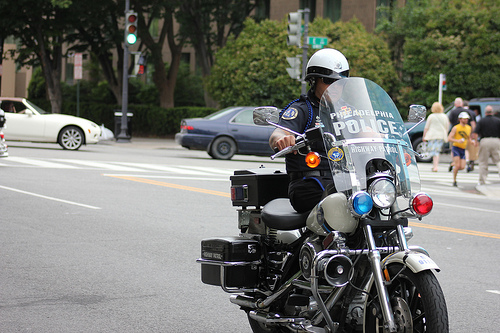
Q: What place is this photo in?
A: It is at the road.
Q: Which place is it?
A: It is a road.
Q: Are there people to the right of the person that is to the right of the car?
A: Yes, there is a person to the right of the man.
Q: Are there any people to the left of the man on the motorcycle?
A: No, the person is to the right of the man.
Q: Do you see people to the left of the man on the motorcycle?
A: No, the person is to the right of the man.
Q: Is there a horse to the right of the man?
A: No, there is a person to the right of the man.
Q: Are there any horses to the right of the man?
A: No, there is a person to the right of the man.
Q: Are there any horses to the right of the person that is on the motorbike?
A: No, there is a person to the right of the man.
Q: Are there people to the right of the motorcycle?
A: Yes, there is a person to the right of the motorcycle.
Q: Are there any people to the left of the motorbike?
A: No, the person is to the right of the motorbike.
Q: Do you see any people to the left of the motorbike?
A: No, the person is to the right of the motorbike.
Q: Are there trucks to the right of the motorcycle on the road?
A: No, there is a person to the right of the motorbike.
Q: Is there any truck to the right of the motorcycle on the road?
A: No, there is a person to the right of the motorbike.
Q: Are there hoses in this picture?
A: No, there are no hoses.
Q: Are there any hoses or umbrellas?
A: No, there are no hoses or umbrellas.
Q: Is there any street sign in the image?
A: Yes, there is a street sign.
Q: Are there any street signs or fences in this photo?
A: Yes, there is a street sign.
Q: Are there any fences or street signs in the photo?
A: Yes, there is a street sign.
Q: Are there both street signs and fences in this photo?
A: No, there is a street sign but no fences.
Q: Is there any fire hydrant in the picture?
A: No, there are no fire hydrants.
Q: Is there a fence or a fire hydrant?
A: No, there are no fire hydrants or fences.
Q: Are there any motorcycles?
A: Yes, there is a motorcycle.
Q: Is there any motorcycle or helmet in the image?
A: Yes, there is a motorcycle.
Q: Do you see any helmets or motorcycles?
A: Yes, there is a motorcycle.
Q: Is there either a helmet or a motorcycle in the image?
A: Yes, there is a motorcycle.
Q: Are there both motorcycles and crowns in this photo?
A: No, there is a motorcycle but no crowns.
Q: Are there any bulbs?
A: No, there are no bulbs.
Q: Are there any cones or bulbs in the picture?
A: No, there are no bulbs or cones.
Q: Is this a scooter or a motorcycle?
A: This is a motorcycle.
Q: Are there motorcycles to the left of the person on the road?
A: Yes, there is a motorcycle to the left of the person.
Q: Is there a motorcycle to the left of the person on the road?
A: Yes, there is a motorcycle to the left of the person.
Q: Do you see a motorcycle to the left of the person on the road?
A: Yes, there is a motorcycle to the left of the person.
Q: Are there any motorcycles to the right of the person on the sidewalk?
A: No, the motorcycle is to the left of the person.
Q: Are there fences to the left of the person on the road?
A: No, there is a motorcycle to the left of the person.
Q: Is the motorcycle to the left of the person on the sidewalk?
A: Yes, the motorcycle is to the left of the person.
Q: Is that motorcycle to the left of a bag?
A: No, the motorcycle is to the left of the person.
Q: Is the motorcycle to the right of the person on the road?
A: No, the motorcycle is to the left of the person.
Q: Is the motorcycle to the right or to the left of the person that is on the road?
A: The motorcycle is to the left of the person.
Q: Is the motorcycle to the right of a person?
A: No, the motorcycle is to the left of a person.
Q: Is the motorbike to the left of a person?
A: Yes, the motorbike is to the left of a person.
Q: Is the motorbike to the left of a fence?
A: No, the motorbike is to the left of a person.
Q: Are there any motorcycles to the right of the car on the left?
A: Yes, there is a motorcycle to the right of the car.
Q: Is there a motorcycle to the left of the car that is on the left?
A: No, the motorcycle is to the right of the car.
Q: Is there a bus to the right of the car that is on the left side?
A: No, there is a motorcycle to the right of the car.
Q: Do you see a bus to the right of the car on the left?
A: No, there is a motorcycle to the right of the car.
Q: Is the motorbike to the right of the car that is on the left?
A: Yes, the motorbike is to the right of the car.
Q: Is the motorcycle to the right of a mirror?
A: No, the motorcycle is to the right of the car.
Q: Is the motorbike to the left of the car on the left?
A: No, the motorbike is to the right of the car.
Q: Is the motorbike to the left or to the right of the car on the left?
A: The motorbike is to the right of the car.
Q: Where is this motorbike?
A: The motorbike is on the road.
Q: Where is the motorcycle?
A: The motorbike is on the road.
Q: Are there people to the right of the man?
A: Yes, there is a person to the right of the man.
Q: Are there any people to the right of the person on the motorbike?
A: Yes, there is a person to the right of the man.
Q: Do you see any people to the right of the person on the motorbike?
A: Yes, there is a person to the right of the man.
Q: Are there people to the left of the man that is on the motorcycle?
A: No, the person is to the right of the man.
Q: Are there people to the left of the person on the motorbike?
A: No, the person is to the right of the man.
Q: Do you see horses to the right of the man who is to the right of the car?
A: No, there is a person to the right of the man.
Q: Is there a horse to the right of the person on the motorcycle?
A: No, there is a person to the right of the man.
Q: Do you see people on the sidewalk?
A: Yes, there is a person on the sidewalk.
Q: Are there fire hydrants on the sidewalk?
A: No, there is a person on the sidewalk.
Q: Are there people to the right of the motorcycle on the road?
A: Yes, there is a person to the right of the motorcycle.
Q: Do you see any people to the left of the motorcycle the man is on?
A: No, the person is to the right of the motorcycle.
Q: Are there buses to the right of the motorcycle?
A: No, there is a person to the right of the motorcycle.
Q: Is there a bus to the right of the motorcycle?
A: No, there is a person to the right of the motorcycle.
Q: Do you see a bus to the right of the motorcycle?
A: No, there is a person to the right of the motorcycle.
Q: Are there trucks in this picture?
A: No, there are no trucks.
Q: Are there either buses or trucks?
A: No, there are no trucks or buses.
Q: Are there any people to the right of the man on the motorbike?
A: Yes, there is a person to the right of the man.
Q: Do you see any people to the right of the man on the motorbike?
A: Yes, there is a person to the right of the man.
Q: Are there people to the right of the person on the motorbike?
A: Yes, there is a person to the right of the man.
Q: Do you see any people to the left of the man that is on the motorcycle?
A: No, the person is to the right of the man.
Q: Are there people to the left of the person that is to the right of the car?
A: No, the person is to the right of the man.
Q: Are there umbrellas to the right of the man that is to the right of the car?
A: No, there is a person to the right of the man.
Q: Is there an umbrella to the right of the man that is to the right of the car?
A: No, there is a person to the right of the man.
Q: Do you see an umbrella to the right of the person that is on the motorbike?
A: No, there is a person to the right of the man.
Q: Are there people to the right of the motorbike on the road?
A: Yes, there is a person to the right of the motorbike.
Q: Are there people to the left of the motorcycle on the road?
A: No, the person is to the right of the motorcycle.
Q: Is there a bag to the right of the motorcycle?
A: No, there is a person to the right of the motorcycle.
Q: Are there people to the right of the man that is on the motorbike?
A: Yes, there is a person to the right of the man.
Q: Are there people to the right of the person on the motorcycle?
A: Yes, there is a person to the right of the man.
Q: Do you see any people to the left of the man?
A: No, the person is to the right of the man.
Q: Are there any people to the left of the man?
A: No, the person is to the right of the man.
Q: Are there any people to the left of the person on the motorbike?
A: No, the person is to the right of the man.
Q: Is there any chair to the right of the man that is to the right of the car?
A: No, there is a person to the right of the man.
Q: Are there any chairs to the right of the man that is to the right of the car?
A: No, there is a person to the right of the man.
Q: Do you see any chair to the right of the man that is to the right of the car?
A: No, there is a person to the right of the man.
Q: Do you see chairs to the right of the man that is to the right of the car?
A: No, there is a person to the right of the man.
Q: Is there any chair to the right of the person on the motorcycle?
A: No, there is a person to the right of the man.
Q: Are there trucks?
A: No, there are no trucks.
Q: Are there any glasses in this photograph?
A: No, there are no glasses.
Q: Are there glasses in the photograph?
A: No, there are no glasses.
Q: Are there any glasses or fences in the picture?
A: No, there are no glasses or fences.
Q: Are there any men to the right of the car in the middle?
A: Yes, there is a man to the right of the car.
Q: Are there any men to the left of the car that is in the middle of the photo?
A: No, the man is to the right of the car.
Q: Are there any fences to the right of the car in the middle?
A: No, there is a man to the right of the car.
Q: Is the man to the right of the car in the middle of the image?
A: Yes, the man is to the right of the car.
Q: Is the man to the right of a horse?
A: No, the man is to the right of the car.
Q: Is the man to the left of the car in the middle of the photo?
A: No, the man is to the right of the car.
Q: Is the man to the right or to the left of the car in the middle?
A: The man is to the right of the car.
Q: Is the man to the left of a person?
A: Yes, the man is to the left of a person.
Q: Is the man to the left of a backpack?
A: No, the man is to the left of a person.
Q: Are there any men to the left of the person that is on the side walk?
A: Yes, there is a man to the left of the person.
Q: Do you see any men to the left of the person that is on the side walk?
A: Yes, there is a man to the left of the person.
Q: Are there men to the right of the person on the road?
A: No, the man is to the left of the person.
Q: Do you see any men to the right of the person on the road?
A: No, the man is to the left of the person.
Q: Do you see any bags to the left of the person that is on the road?
A: No, there is a man to the left of the person.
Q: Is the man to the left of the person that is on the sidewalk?
A: Yes, the man is to the left of the person.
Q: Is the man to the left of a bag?
A: No, the man is to the left of the person.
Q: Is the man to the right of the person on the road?
A: No, the man is to the left of the person.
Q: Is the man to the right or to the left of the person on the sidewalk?
A: The man is to the left of the person.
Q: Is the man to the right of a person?
A: No, the man is to the left of a person.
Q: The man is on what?
A: The man is on the motorcycle.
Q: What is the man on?
A: The man is on the motorcycle.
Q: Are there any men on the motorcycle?
A: Yes, there is a man on the motorcycle.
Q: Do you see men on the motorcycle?
A: Yes, there is a man on the motorcycle.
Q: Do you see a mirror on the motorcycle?
A: No, there is a man on the motorcycle.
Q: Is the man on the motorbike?
A: Yes, the man is on the motorbike.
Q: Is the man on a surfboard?
A: No, the man is on the motorbike.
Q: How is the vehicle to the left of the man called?
A: The vehicle is a car.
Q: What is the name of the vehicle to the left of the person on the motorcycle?
A: The vehicle is a car.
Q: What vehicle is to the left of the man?
A: The vehicle is a car.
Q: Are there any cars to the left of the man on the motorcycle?
A: Yes, there is a car to the left of the man.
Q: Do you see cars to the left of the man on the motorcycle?
A: Yes, there is a car to the left of the man.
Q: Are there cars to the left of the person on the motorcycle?
A: Yes, there is a car to the left of the man.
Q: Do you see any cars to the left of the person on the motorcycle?
A: Yes, there is a car to the left of the man.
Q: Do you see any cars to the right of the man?
A: No, the car is to the left of the man.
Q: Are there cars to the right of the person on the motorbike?
A: No, the car is to the left of the man.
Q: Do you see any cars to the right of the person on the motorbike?
A: No, the car is to the left of the man.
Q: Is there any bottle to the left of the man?
A: No, there is a car to the left of the man.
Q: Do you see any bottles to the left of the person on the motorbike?
A: No, there is a car to the left of the man.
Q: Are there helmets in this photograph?
A: Yes, there is a helmet.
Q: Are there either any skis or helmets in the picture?
A: Yes, there is a helmet.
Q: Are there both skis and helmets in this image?
A: No, there is a helmet but no skis.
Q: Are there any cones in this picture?
A: No, there are no cones.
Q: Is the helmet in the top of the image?
A: Yes, the helmet is in the top of the image.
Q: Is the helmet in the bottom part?
A: No, the helmet is in the top of the image.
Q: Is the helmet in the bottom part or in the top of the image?
A: The helmet is in the top of the image.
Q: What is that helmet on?
A: The helmet is on the motorbike.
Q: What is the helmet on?
A: The helmet is on the motorbike.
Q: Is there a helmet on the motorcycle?
A: Yes, there is a helmet on the motorcycle.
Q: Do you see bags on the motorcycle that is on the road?
A: No, there is a helmet on the motorcycle.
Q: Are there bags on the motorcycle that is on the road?
A: No, there is a helmet on the motorcycle.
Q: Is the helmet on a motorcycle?
A: Yes, the helmet is on a motorcycle.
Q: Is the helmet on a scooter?
A: No, the helmet is on a motorcycle.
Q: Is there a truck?
A: No, there are no trucks.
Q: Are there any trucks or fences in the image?
A: No, there are no trucks or fences.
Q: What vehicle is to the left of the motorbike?
A: The vehicle is a car.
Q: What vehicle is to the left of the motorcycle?
A: The vehicle is a car.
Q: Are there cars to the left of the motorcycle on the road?
A: Yes, there is a car to the left of the motorbike.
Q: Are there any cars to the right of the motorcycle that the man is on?
A: No, the car is to the left of the motorcycle.